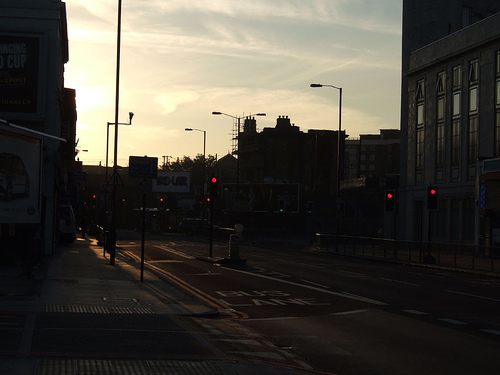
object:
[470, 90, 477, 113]
windows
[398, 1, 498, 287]
building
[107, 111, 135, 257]
traffic cam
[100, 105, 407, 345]
tall street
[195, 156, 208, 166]
leaves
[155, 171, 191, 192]
sign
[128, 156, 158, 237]
building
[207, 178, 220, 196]
lamp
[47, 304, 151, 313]
manhole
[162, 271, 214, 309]
line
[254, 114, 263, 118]
street light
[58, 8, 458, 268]
dawn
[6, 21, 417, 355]
scene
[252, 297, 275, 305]
writing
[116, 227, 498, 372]
pavement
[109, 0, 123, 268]
pole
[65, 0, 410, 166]
sky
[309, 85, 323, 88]
lights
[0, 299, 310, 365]
driveway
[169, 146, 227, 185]
tree top